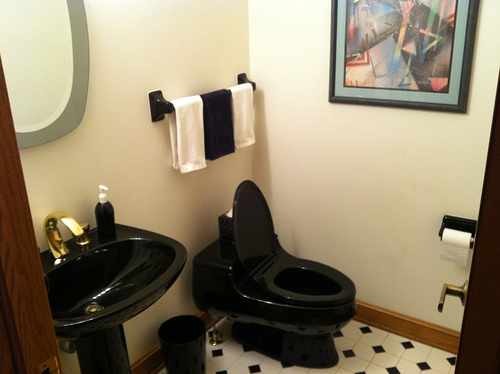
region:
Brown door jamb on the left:
[5, 217, 31, 301]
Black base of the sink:
[83, 341, 118, 371]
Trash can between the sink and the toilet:
[157, 312, 208, 372]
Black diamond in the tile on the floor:
[368, 340, 390, 359]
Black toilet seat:
[262, 251, 353, 303]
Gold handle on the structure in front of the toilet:
[431, 273, 473, 312]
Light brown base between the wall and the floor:
[367, 312, 402, 324]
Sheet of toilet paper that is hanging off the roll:
[433, 244, 472, 264]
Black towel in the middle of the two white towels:
[199, 89, 239, 159]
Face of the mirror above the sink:
[8, 10, 48, 78]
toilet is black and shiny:
[190, 179, 362, 370]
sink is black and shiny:
[37, 220, 187, 372]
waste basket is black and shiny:
[158, 314, 209, 373]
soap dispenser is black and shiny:
[95, 201, 120, 236]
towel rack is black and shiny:
[144, 72, 267, 122]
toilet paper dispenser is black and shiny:
[439, 211, 477, 248]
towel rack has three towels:
[168, 82, 260, 174]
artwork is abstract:
[326, 0, 484, 122]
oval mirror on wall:
[1, 1, 91, 151]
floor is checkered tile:
[143, 313, 457, 370]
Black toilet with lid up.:
[189, 179, 360, 369]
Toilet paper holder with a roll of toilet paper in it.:
[438, 210, 475, 267]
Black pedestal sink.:
[39, 176, 189, 372]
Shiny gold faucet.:
[40, 205, 91, 260]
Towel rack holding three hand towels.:
[145, 71, 258, 173]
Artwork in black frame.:
[327, 19, 475, 114]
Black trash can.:
[154, 312, 210, 372]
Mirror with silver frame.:
[2, 18, 89, 150]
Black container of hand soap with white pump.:
[94, 182, 116, 242]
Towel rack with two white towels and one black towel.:
[148, 71, 258, 175]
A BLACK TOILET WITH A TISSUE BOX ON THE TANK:
[188, 173, 370, 370]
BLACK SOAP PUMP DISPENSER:
[84, 182, 137, 253]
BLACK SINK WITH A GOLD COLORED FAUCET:
[39, 178, 190, 371]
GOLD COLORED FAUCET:
[38, 207, 102, 268]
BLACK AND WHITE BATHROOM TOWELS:
[145, 67, 292, 178]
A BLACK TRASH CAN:
[150, 311, 245, 372]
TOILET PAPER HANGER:
[431, 200, 480, 272]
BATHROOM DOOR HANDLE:
[428, 267, 473, 330]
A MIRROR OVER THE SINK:
[6, 0, 113, 154]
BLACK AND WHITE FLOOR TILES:
[354, 320, 418, 371]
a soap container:
[85, 179, 126, 233]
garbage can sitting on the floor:
[158, 313, 222, 372]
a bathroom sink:
[29, 200, 173, 371]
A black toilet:
[196, 207, 378, 370]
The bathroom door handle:
[438, 258, 479, 370]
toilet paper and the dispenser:
[436, 206, 487, 271]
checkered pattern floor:
[355, 335, 439, 372]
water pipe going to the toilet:
[203, 308, 241, 361]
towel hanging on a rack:
[142, 83, 301, 168]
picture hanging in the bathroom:
[299, 4, 496, 148]